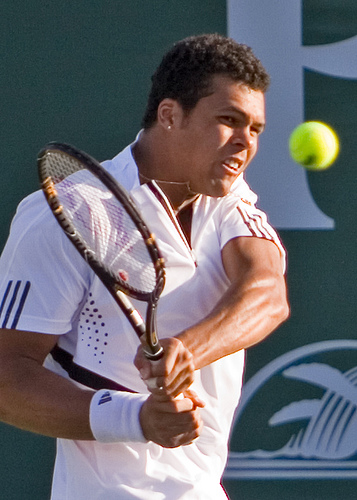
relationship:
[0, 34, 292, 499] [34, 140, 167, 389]
man holding racket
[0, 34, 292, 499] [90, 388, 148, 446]
man wearing wrist band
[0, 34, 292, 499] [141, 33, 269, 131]
man has hair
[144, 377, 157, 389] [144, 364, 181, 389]
bandage on finger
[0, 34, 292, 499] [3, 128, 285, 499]
man wearing shirt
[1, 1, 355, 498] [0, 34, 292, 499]
wall behind man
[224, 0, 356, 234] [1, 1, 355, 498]
letter on wall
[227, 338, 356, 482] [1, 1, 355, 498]
picture on wall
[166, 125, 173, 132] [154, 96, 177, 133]
earring in ear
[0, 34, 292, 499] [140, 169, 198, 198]
man wearing necklace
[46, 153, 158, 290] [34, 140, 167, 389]
strings on racket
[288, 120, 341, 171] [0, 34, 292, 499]
ball in front of man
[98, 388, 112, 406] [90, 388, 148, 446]
adidas logo on wrist band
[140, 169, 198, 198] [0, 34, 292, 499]
necklace on man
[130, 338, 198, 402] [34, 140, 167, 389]
hand holding racket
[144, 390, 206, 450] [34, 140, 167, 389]
hand holding racket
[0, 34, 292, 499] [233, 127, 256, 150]
man has nose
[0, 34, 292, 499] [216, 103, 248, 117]
man has eyebrow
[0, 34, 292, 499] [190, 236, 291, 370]
man has arm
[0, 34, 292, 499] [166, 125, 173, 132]
man wearing earring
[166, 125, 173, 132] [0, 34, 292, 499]
earring on man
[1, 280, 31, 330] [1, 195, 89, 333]
stripes on sleeve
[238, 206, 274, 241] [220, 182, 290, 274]
stripes on sleeve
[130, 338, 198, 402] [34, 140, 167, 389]
hand on racket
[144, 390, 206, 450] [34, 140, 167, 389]
hand on racket